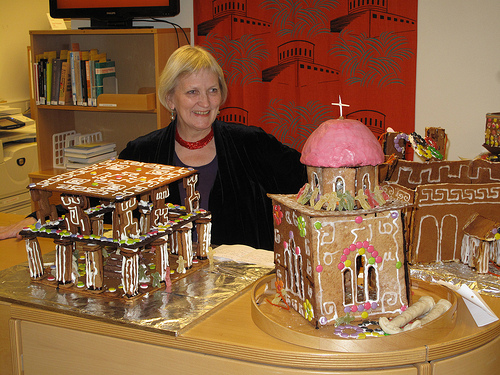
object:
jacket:
[24, 121, 307, 250]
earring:
[169, 112, 175, 121]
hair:
[157, 45, 227, 114]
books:
[93, 58, 115, 108]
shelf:
[35, 106, 157, 113]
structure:
[16, 158, 209, 304]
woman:
[0, 45, 313, 253]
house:
[0, 0, 497, 375]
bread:
[267, 116, 411, 327]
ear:
[164, 92, 175, 110]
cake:
[21, 160, 213, 303]